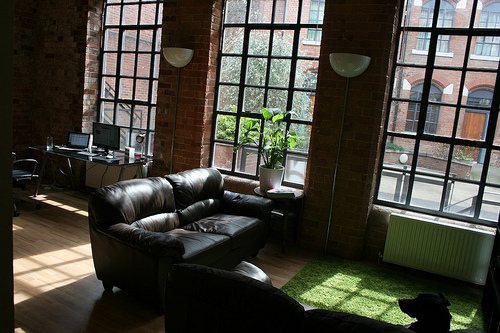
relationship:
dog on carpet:
[397, 285, 456, 327] [321, 265, 418, 327]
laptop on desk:
[58, 126, 101, 160] [38, 141, 144, 171]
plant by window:
[240, 97, 295, 197] [203, 1, 327, 195]